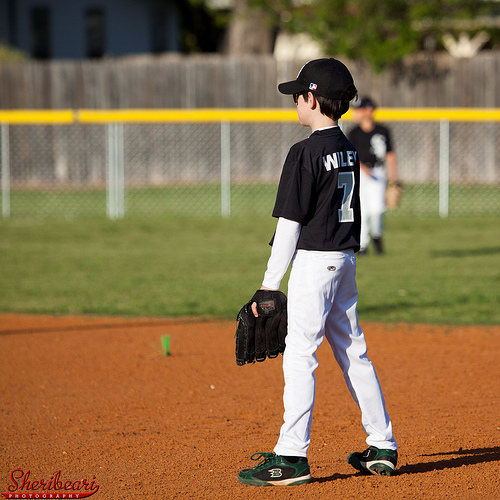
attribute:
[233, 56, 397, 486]
boy — throwing ball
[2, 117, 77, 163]
square — metal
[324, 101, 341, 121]
hair — black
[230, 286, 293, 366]
baseball glove — black 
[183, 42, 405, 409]
boy — black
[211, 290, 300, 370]
glove — black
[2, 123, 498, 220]
fence — metal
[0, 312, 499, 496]
turf — brown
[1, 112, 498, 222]
fence — wooden, small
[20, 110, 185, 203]
fence — metal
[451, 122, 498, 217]
square — metal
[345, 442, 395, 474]
shoe — black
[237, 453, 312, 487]
shoe — black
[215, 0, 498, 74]
leaves — green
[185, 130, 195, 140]
square — metal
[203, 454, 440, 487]
cleats — green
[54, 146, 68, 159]
square — metal